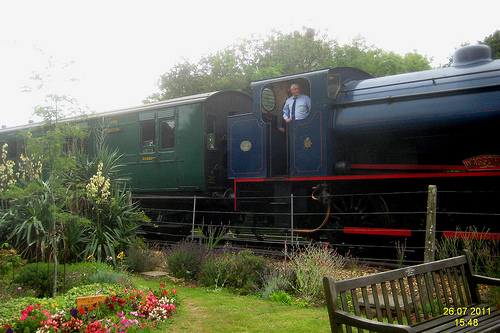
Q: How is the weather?
A: It is overcast.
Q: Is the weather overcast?
A: Yes, it is overcast.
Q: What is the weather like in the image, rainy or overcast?
A: It is overcast.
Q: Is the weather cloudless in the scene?
A: No, it is overcast.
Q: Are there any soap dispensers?
A: No, there are no soap dispensers.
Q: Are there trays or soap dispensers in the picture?
A: No, there are no soap dispensers or trays.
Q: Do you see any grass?
A: Yes, there is grass.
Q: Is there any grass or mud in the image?
A: Yes, there is grass.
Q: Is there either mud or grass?
A: Yes, there is grass.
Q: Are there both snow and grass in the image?
A: No, there is grass but no snow.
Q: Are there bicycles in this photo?
A: No, there are no bicycles.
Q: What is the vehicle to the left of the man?
A: The vehicle is a car.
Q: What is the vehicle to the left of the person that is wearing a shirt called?
A: The vehicle is a car.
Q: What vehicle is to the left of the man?
A: The vehicle is a car.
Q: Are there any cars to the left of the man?
A: Yes, there is a car to the left of the man.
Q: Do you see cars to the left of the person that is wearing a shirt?
A: Yes, there is a car to the left of the man.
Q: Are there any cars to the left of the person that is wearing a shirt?
A: Yes, there is a car to the left of the man.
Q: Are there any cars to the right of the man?
A: No, the car is to the left of the man.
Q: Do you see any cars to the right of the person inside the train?
A: No, the car is to the left of the man.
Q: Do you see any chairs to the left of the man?
A: No, there is a car to the left of the man.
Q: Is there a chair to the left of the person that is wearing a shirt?
A: No, there is a car to the left of the man.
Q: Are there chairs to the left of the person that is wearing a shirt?
A: No, there is a car to the left of the man.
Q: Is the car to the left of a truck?
A: No, the car is to the left of a man.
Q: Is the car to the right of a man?
A: No, the car is to the left of a man.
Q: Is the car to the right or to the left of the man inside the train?
A: The car is to the left of the man.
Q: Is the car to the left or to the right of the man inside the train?
A: The car is to the left of the man.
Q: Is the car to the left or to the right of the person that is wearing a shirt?
A: The car is to the left of the man.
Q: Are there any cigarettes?
A: No, there are no cigarettes.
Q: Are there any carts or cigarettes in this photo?
A: No, there are no cigarettes or carts.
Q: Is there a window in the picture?
A: Yes, there is a window.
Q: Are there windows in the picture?
A: Yes, there is a window.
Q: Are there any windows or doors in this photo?
A: Yes, there is a window.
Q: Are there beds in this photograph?
A: Yes, there is a bed.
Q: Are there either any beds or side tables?
A: Yes, there is a bed.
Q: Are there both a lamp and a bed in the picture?
A: No, there is a bed but no lamps.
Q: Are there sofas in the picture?
A: No, there are no sofas.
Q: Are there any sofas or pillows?
A: No, there are no sofas or pillows.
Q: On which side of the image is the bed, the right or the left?
A: The bed is on the left of the image.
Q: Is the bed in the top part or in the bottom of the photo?
A: The bed is in the bottom of the image.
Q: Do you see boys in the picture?
A: No, there are no boys.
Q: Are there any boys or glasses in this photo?
A: No, there are no boys or glasses.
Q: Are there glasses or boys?
A: No, there are no boys or glasses.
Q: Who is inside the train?
A: The man is inside the train.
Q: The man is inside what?
A: The man is inside the train.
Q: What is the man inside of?
A: The man is inside the train.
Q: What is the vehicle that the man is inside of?
A: The vehicle is a train.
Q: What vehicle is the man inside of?
A: The man is inside the train.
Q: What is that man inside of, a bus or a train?
A: The man is inside a train.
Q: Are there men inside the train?
A: Yes, there is a man inside the train.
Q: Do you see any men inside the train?
A: Yes, there is a man inside the train.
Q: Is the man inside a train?
A: Yes, the man is inside a train.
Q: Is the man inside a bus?
A: No, the man is inside a train.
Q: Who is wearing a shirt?
A: The man is wearing a shirt.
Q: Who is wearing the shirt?
A: The man is wearing a shirt.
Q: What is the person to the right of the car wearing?
A: The man is wearing a shirt.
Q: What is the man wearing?
A: The man is wearing a shirt.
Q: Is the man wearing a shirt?
A: Yes, the man is wearing a shirt.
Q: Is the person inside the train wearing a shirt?
A: Yes, the man is wearing a shirt.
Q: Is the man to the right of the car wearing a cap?
A: No, the man is wearing a shirt.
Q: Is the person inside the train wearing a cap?
A: No, the man is wearing a shirt.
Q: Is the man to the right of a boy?
A: No, the man is to the right of the car.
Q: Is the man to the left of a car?
A: No, the man is to the right of a car.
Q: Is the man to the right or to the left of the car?
A: The man is to the right of the car.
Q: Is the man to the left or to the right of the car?
A: The man is to the right of the car.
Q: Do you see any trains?
A: Yes, there is a train.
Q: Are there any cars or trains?
A: Yes, there is a train.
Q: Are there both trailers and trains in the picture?
A: No, there is a train but no trailers.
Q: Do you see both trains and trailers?
A: No, there is a train but no trailers.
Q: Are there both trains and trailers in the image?
A: No, there is a train but no trailers.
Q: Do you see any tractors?
A: No, there are no tractors.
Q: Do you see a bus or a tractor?
A: No, there are no tractors or buses.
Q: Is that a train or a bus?
A: That is a train.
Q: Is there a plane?
A: No, there are no airplanes.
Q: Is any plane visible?
A: No, there are no airplanes.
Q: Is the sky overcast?
A: Yes, the sky is overcast.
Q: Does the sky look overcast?
A: Yes, the sky is overcast.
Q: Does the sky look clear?
A: No, the sky is overcast.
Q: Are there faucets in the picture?
A: No, there are no faucets.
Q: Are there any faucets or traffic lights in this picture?
A: No, there are no faucets or traffic lights.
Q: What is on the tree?
A: The leaves are on the tree.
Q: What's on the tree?
A: The leaves are on the tree.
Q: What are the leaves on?
A: The leaves are on the tree.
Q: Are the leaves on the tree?
A: Yes, the leaves are on the tree.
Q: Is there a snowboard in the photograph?
A: No, there are no snowboards.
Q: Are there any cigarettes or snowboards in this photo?
A: No, there are no snowboards or cigarettes.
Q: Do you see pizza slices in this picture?
A: No, there are no pizza slices.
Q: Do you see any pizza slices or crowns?
A: No, there are no pizza slices or crowns.